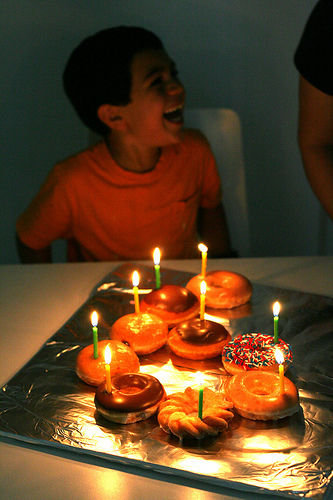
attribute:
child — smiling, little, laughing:
[13, 22, 238, 263]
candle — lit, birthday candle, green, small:
[197, 371, 205, 418]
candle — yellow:
[278, 360, 286, 396]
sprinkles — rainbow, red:
[219, 332, 292, 372]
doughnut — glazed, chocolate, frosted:
[93, 371, 166, 422]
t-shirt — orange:
[12, 127, 225, 263]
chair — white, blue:
[182, 106, 253, 258]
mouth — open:
[161, 100, 187, 127]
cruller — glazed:
[157, 385, 233, 439]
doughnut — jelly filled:
[109, 312, 167, 355]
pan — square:
[0, 262, 332, 497]